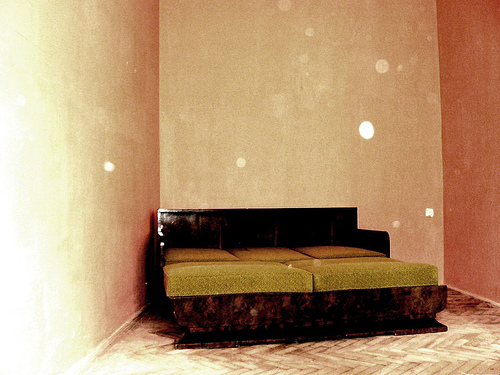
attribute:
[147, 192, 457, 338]
bed — green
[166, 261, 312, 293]
cushion — green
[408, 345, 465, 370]
floor — wooden, patterned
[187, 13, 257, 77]
wall — brown, smooth, pink, orange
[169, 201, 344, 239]
headboard — brown, wooden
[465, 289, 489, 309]
molding — white, thin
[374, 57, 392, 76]
spot — white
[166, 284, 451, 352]
foot board — dark colored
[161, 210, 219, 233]
wood — brown, dark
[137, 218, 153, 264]
shadow — black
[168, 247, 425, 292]
mattress — green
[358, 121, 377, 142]
orb — white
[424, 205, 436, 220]
square — white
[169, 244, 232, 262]
pillow — green